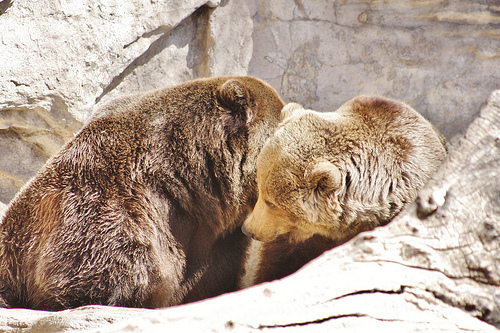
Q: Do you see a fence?
A: No, there are no fences.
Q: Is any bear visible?
A: Yes, there is a bear.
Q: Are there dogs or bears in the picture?
A: Yes, there is a bear.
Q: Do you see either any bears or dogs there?
A: Yes, there is a bear.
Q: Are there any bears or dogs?
A: Yes, there is a bear.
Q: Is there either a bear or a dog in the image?
A: Yes, there is a bear.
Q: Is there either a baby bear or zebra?
A: Yes, there is a baby bear.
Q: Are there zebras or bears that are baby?
A: Yes, the bear is a baby.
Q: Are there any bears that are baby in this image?
A: Yes, there is a baby bear.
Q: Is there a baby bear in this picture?
A: Yes, there is a baby bear.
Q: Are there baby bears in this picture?
A: Yes, there is a baby bear.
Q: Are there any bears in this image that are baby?
A: Yes, there is a bear that is a baby.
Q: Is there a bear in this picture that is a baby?
A: Yes, there is a bear that is a baby.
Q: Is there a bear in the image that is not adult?
A: Yes, there is an baby bear.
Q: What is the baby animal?
A: The animal is a bear.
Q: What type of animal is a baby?
A: The animal is a bear.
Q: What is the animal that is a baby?
A: The animal is a bear.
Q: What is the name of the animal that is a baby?
A: The animal is a bear.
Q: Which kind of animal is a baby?
A: The animal is a bear.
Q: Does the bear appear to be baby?
A: Yes, the bear is a baby.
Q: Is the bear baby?
A: Yes, the bear is a baby.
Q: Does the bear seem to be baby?
A: Yes, the bear is a baby.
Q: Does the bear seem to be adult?
A: No, the bear is a baby.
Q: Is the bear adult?
A: No, the bear is a baby.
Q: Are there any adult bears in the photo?
A: No, there is a bear but it is a baby.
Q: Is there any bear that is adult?
A: No, there is a bear but it is a baby.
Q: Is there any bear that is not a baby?
A: No, there is a bear but it is a baby.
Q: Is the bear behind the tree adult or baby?
A: The bear is a baby.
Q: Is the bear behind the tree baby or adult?
A: The bear is a baby.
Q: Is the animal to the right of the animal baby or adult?
A: The bear is a baby.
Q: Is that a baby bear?
A: Yes, that is a baby bear.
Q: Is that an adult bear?
A: No, that is a baby bear.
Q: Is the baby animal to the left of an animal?
A: No, the bear is to the right of an animal.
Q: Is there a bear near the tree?
A: Yes, there is a bear near the tree.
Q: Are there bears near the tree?
A: Yes, there is a bear near the tree.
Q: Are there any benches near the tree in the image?
A: No, there is a bear near the tree.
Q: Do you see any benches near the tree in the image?
A: No, there is a bear near the tree.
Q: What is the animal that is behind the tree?
A: The animal is a bear.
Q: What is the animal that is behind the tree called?
A: The animal is a bear.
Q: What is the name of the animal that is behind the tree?
A: The animal is a bear.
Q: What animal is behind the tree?
A: The animal is a bear.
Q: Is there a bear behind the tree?
A: Yes, there is a bear behind the tree.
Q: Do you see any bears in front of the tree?
A: No, the bear is behind the tree.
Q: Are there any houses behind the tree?
A: No, there is a bear behind the tree.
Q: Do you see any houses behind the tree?
A: No, there is a bear behind the tree.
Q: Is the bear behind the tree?
A: Yes, the bear is behind the tree.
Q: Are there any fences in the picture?
A: No, there are no fences.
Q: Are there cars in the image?
A: No, there are no cars.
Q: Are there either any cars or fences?
A: No, there are no cars or fences.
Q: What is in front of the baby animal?
A: The tree is in front of the bear.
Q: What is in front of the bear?
A: The tree is in front of the bear.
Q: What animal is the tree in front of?
A: The tree is in front of the bear.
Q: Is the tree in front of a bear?
A: Yes, the tree is in front of a bear.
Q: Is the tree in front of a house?
A: No, the tree is in front of a bear.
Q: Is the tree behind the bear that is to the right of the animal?
A: No, the tree is in front of the bear.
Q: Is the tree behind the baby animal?
A: No, the tree is in front of the bear.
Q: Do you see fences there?
A: No, there are no fences.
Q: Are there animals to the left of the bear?
A: Yes, there is an animal to the left of the bear.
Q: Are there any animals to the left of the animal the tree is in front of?
A: Yes, there is an animal to the left of the bear.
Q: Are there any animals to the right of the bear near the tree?
A: No, the animal is to the left of the bear.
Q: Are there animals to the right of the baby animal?
A: No, the animal is to the left of the bear.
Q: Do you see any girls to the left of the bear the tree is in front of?
A: No, there is an animal to the left of the bear.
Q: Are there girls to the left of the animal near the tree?
A: No, there is an animal to the left of the bear.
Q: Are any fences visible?
A: No, there are no fences.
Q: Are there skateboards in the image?
A: No, there are no skateboards.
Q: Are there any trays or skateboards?
A: No, there are no skateboards or trays.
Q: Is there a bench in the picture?
A: No, there are no benches.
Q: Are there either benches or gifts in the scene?
A: No, there are no benches or gifts.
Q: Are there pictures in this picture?
A: No, there are no pictures.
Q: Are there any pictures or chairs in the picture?
A: No, there are no pictures or chairs.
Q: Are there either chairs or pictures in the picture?
A: No, there are no pictures or chairs.